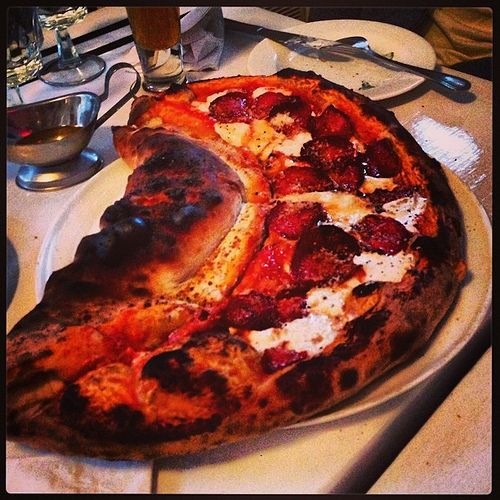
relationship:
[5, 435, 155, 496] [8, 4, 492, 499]
napkin on table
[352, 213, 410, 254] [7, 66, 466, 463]
pepperoni on pizza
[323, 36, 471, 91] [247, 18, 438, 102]
fork on plate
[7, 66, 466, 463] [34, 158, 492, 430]
pizza on dish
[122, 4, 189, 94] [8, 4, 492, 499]
glass on table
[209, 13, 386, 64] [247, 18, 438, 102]
knife on plate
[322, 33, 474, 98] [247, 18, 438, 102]
fork on plate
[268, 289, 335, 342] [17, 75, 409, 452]
cheese on pizza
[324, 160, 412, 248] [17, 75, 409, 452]
cheese on pizza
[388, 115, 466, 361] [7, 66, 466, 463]
crust on pizza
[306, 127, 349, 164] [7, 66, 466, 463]
pepperoni on pizza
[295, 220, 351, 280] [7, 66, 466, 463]
pepperoni on pizza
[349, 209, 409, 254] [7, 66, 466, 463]
pepperoni on pizza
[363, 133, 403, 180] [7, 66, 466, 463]
pepperoni on pizza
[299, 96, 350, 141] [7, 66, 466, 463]
pepperoni on pizza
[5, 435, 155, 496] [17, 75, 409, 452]
napkin beside pizza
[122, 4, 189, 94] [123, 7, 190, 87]
glass with beer